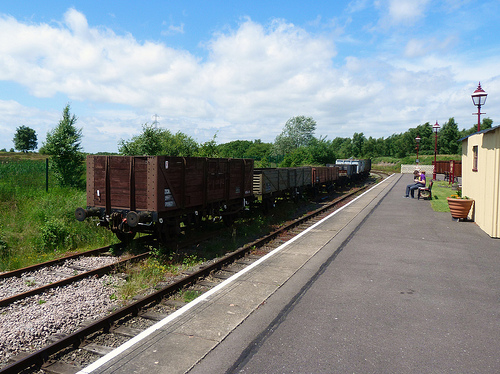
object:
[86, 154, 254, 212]
train car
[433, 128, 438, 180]
pole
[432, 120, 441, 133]
light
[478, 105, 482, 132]
pole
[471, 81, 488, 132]
lamp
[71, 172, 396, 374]
white edge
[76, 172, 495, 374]
concrete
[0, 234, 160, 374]
railroad tracks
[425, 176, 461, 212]
grass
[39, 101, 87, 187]
tree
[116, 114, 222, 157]
tree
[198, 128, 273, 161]
tree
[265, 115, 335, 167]
tree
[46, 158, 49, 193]
post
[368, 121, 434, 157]
trees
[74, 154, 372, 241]
carriages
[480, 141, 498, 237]
wall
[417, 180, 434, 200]
bench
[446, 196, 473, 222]
flower pot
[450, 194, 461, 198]
flowers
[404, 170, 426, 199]
person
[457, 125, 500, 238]
building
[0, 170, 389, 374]
rail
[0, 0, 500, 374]
outside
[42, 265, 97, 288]
part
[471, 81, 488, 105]
light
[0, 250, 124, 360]
gravel